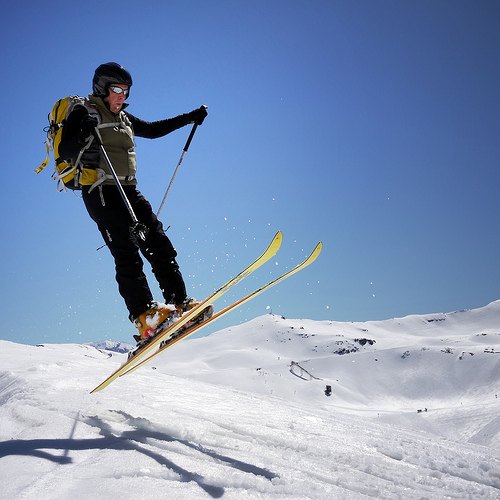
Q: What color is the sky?
A: Blue.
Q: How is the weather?
A: Clear.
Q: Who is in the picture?
A: A man.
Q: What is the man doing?
A: Skiing.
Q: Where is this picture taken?
A: A ski slope.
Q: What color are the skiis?
A: Yellow.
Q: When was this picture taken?
A: Daytime.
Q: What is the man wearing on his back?
A: A backpack.